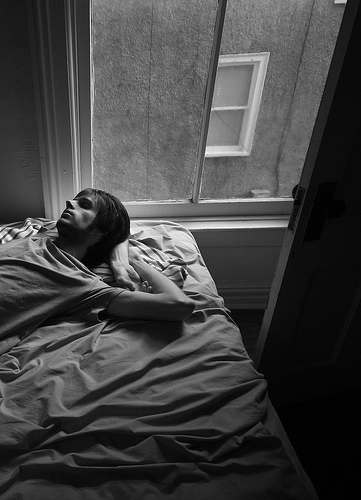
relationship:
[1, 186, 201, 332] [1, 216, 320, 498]
guy laying on bed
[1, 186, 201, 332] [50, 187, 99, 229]
guy has face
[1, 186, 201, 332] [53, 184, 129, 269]
guy has head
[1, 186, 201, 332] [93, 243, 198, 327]
guy has arm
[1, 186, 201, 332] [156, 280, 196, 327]
guy has elbow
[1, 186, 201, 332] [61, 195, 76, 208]
guy has nose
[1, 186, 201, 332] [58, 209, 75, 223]
guy has mouth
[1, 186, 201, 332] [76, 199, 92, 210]
guy has eye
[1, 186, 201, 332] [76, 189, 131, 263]
guy has hair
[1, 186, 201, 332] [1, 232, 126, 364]
guy has shirt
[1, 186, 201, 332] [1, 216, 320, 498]
guy laying in bed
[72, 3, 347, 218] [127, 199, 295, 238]
window has ledge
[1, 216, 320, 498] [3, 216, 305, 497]
bed has sheets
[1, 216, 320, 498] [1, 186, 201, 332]
bed has guy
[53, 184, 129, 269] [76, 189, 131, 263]
head has hair